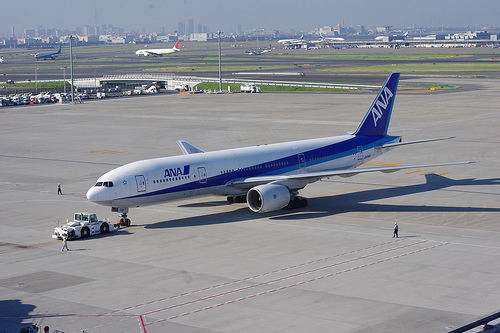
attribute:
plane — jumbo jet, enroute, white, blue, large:
[69, 65, 477, 217]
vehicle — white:
[53, 209, 116, 241]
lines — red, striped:
[100, 235, 435, 320]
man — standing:
[57, 232, 74, 249]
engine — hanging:
[241, 183, 300, 216]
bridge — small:
[54, 64, 201, 92]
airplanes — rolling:
[23, 41, 318, 57]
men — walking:
[47, 178, 85, 257]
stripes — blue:
[259, 141, 329, 173]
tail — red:
[169, 38, 182, 53]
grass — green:
[196, 81, 333, 92]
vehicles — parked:
[1, 85, 109, 106]